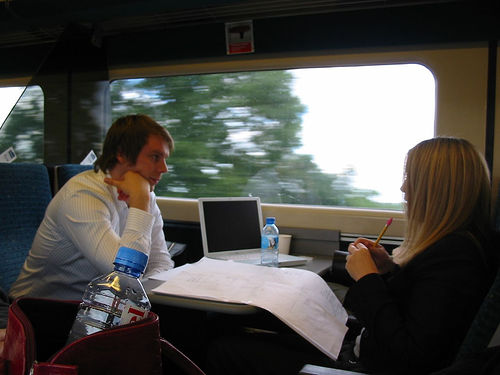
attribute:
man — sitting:
[0, 112, 177, 359]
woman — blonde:
[341, 133, 498, 373]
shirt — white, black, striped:
[9, 163, 177, 296]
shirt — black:
[333, 230, 489, 375]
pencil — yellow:
[369, 215, 395, 249]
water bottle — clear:
[67, 247, 153, 336]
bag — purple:
[1, 296, 166, 373]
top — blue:
[114, 246, 150, 277]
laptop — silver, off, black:
[192, 193, 313, 269]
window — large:
[87, 63, 443, 214]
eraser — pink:
[380, 217, 390, 230]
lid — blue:
[113, 246, 152, 277]